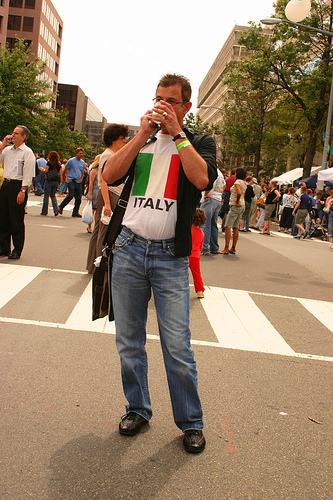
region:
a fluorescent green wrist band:
[175, 139, 191, 150]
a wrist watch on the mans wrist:
[172, 130, 188, 139]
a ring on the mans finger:
[162, 110, 168, 117]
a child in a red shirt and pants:
[189, 208, 205, 298]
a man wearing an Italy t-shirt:
[123, 133, 184, 240]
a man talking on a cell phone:
[0, 125, 33, 259]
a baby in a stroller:
[307, 208, 329, 239]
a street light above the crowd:
[260, 16, 331, 167]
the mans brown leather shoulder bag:
[85, 152, 140, 321]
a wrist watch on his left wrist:
[18, 187, 27, 195]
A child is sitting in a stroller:
[304, 204, 329, 244]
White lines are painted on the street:
[0, 260, 331, 361]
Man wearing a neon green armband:
[132, 69, 201, 150]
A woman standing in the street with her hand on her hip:
[222, 162, 246, 255]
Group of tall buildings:
[0, 0, 106, 131]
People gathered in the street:
[217, 160, 308, 238]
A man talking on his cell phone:
[3, 118, 33, 181]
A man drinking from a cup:
[134, 70, 201, 136]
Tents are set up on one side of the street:
[269, 158, 329, 211]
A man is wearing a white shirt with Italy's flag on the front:
[120, 72, 201, 238]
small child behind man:
[186, 207, 208, 295]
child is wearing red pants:
[188, 256, 205, 289]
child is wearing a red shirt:
[188, 226, 204, 258]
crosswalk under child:
[0, 262, 332, 361]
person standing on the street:
[218, 167, 249, 254]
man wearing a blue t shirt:
[52, 144, 86, 213]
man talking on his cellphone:
[0, 124, 38, 261]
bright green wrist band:
[175, 140, 189, 151]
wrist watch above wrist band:
[172, 130, 185, 142]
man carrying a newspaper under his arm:
[16, 158, 35, 177]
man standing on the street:
[89, 74, 217, 457]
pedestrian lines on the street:
[0, 262, 332, 360]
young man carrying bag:
[90, 74, 219, 455]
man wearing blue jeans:
[88, 73, 218, 454]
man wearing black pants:
[0, 123, 38, 258]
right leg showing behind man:
[186, 257, 206, 297]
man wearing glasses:
[90, 72, 216, 452]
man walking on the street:
[55, 147, 83, 214]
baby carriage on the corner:
[306, 205, 327, 238]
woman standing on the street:
[220, 165, 248, 257]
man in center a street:
[95, 77, 227, 462]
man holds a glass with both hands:
[92, 67, 222, 466]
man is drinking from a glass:
[88, 66, 225, 470]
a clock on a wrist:
[164, 122, 183, 141]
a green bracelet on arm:
[176, 136, 191, 154]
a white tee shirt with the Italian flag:
[121, 125, 193, 241]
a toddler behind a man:
[116, 64, 219, 308]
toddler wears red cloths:
[190, 208, 217, 302]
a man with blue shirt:
[58, 142, 90, 220]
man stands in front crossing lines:
[2, 122, 61, 337]